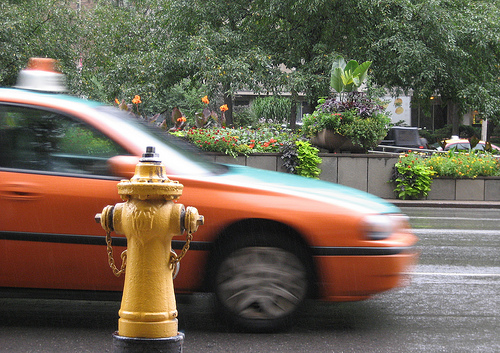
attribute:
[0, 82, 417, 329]
car — orange